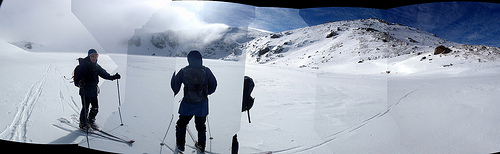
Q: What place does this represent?
A: It represents the sidewalk.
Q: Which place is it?
A: It is a sidewalk.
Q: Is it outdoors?
A: Yes, it is outdoors.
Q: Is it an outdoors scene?
A: Yes, it is outdoors.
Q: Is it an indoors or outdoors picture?
A: It is outdoors.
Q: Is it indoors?
A: No, it is outdoors.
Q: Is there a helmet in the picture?
A: No, there are no helmets.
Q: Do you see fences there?
A: No, there are no fences.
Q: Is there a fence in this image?
A: No, there are no fences.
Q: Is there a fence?
A: No, there are no fences.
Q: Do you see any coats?
A: Yes, there is a coat.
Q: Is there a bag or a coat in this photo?
A: Yes, there is a coat.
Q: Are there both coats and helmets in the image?
A: No, there is a coat but no helmets.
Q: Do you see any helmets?
A: No, there are no helmets.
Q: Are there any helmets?
A: No, there are no helmets.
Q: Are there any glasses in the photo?
A: No, there are no glasses.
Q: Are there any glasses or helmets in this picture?
A: No, there are no glasses or helmets.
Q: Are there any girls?
A: No, there are no girls.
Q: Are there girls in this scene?
A: No, there are no girls.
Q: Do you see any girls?
A: No, there are no girls.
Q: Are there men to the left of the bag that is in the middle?
A: Yes, there is a man to the left of the backpack.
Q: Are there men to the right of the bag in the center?
A: No, the man is to the left of the backpack.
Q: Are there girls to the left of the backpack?
A: No, there is a man to the left of the backpack.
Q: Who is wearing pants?
A: The man is wearing pants.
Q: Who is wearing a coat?
A: The man is wearing a coat.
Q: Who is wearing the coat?
A: The man is wearing a coat.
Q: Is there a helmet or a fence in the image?
A: No, there are no helmets or fences.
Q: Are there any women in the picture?
A: No, there are no women.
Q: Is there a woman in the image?
A: No, there are no women.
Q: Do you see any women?
A: No, there are no women.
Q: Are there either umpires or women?
A: No, there are no women or umpires.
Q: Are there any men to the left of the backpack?
A: Yes, there is a man to the left of the backpack.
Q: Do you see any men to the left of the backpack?
A: Yes, there is a man to the left of the backpack.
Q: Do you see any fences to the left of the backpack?
A: No, there is a man to the left of the backpack.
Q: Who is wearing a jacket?
A: The man is wearing a jacket.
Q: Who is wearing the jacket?
A: The man is wearing a jacket.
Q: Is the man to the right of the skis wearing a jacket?
A: Yes, the man is wearing a jacket.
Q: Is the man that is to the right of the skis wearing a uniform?
A: No, the man is wearing a jacket.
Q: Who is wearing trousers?
A: The man is wearing trousers.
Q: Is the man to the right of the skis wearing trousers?
A: Yes, the man is wearing trousers.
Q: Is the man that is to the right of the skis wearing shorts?
A: No, the man is wearing trousers.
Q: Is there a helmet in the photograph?
A: No, there are no helmets.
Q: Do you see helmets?
A: No, there are no helmets.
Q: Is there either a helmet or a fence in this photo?
A: No, there are no helmets or fences.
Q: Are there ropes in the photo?
A: No, there are no ropes.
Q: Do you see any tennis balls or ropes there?
A: No, there are no ropes or tennis balls.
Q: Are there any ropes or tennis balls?
A: No, there are no ropes or tennis balls.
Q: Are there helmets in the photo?
A: No, there are no helmets.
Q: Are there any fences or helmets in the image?
A: No, there are no helmets or fences.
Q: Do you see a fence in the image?
A: No, there are no fences.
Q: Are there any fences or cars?
A: No, there are no fences or cars.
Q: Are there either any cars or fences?
A: No, there are no fences or cars.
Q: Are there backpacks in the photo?
A: Yes, there is a backpack.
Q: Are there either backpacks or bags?
A: Yes, there is a backpack.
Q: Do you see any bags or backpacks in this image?
A: Yes, there is a backpack.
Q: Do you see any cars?
A: No, there are no cars.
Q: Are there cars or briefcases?
A: No, there are no cars or briefcases.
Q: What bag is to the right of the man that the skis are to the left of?
A: The bag is a backpack.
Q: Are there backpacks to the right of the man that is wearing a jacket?
A: Yes, there is a backpack to the right of the man.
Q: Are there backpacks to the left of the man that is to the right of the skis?
A: No, the backpack is to the right of the man.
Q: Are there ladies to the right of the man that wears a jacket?
A: No, there is a backpack to the right of the man.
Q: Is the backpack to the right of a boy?
A: No, the backpack is to the right of a man.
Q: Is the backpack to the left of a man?
A: No, the backpack is to the right of a man.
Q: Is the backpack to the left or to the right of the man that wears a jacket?
A: The backpack is to the right of the man.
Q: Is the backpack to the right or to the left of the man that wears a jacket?
A: The backpack is to the right of the man.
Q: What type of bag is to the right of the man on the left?
A: The bag is a backpack.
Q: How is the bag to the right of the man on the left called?
A: The bag is a backpack.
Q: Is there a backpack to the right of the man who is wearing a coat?
A: Yes, there is a backpack to the right of the man.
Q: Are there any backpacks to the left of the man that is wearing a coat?
A: No, the backpack is to the right of the man.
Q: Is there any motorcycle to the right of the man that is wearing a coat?
A: No, there is a backpack to the right of the man.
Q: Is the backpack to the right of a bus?
A: No, the backpack is to the right of a man.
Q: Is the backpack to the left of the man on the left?
A: No, the backpack is to the right of the man.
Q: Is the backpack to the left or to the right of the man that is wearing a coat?
A: The backpack is to the right of the man.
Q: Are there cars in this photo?
A: No, there are no cars.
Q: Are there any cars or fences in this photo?
A: No, there are no cars or fences.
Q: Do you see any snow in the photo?
A: Yes, there is snow.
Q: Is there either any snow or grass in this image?
A: Yes, there is snow.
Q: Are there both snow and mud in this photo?
A: No, there is snow but no mud.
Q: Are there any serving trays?
A: No, there are no serving trays.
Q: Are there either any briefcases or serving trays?
A: No, there are no serving trays or briefcases.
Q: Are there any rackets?
A: No, there are no rackets.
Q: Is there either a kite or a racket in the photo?
A: No, there are no rackets or kites.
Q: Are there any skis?
A: Yes, there are skis.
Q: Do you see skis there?
A: Yes, there are skis.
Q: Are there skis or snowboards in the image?
A: Yes, there are skis.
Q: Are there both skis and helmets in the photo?
A: No, there are skis but no helmets.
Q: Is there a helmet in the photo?
A: No, there are no helmets.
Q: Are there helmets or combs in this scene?
A: No, there are no helmets or combs.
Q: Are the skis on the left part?
A: Yes, the skis are on the left of the image.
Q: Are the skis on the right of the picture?
A: No, the skis are on the left of the image.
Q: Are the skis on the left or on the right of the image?
A: The skis are on the left of the image.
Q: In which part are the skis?
A: The skis are on the left of the image.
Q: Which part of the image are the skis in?
A: The skis are on the left of the image.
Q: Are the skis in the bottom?
A: Yes, the skis are in the bottom of the image.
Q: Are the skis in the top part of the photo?
A: No, the skis are in the bottom of the image.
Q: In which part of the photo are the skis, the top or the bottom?
A: The skis are in the bottom of the image.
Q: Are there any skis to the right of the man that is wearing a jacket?
A: No, the skis are to the left of the man.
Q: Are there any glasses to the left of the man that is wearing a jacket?
A: No, there are skis to the left of the man.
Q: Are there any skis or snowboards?
A: Yes, there are skis.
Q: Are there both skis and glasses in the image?
A: No, there are skis but no glasses.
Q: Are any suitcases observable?
A: No, there are no suitcases.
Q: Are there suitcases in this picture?
A: No, there are no suitcases.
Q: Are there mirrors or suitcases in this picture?
A: No, there are no suitcases or mirrors.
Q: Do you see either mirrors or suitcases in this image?
A: No, there are no suitcases or mirrors.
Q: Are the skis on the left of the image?
A: Yes, the skis are on the left of the image.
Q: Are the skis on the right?
A: No, the skis are on the left of the image.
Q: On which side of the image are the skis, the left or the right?
A: The skis are on the left of the image.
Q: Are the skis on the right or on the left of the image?
A: The skis are on the left of the image.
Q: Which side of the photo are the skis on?
A: The skis are on the left of the image.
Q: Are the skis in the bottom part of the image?
A: Yes, the skis are in the bottom of the image.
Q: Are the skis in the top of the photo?
A: No, the skis are in the bottom of the image.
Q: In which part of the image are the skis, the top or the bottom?
A: The skis are in the bottom of the image.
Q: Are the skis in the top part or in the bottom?
A: The skis are in the bottom of the image.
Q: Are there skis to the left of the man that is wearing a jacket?
A: Yes, there are skis to the left of the man.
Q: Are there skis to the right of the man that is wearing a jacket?
A: No, the skis are to the left of the man.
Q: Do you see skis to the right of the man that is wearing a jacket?
A: No, the skis are to the left of the man.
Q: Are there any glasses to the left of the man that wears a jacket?
A: No, there are skis to the left of the man.